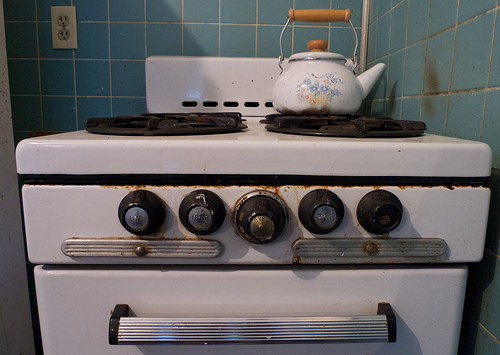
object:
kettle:
[268, 6, 389, 117]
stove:
[12, 103, 500, 355]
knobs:
[116, 187, 407, 246]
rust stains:
[108, 178, 397, 198]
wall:
[14, 3, 138, 107]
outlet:
[49, 4, 77, 50]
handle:
[287, 6, 352, 23]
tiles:
[369, 6, 498, 118]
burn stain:
[419, 48, 449, 115]